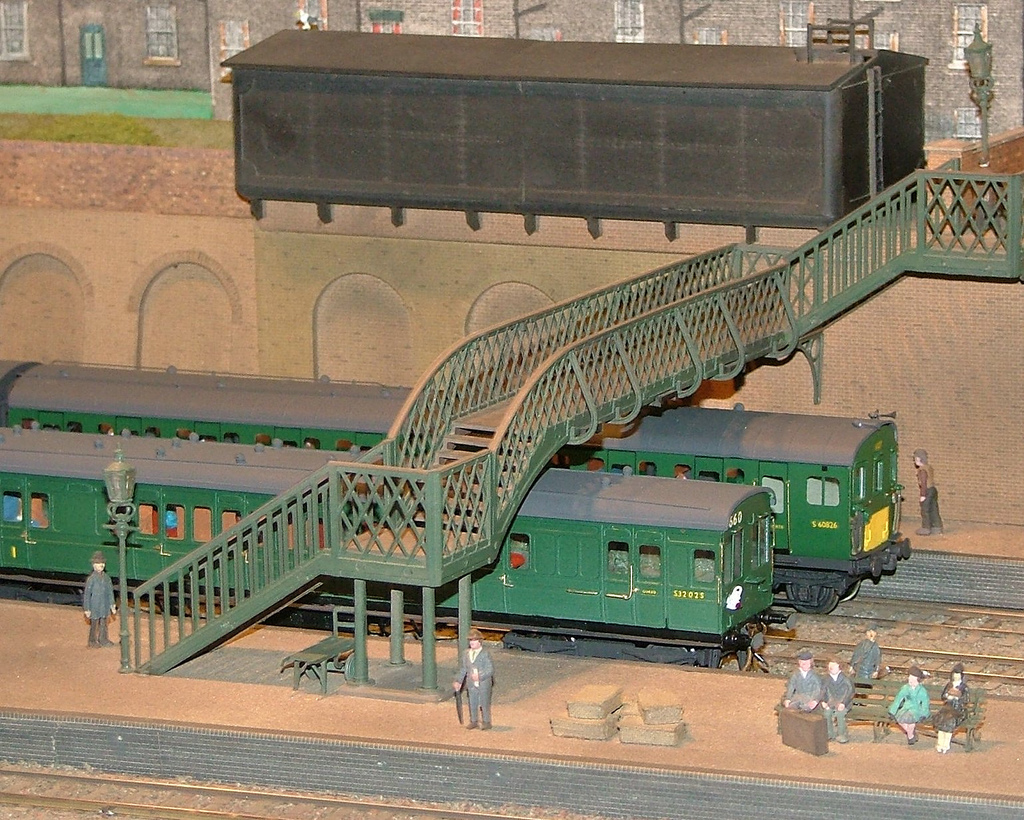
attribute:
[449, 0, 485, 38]
window — glass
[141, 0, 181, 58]
window — glass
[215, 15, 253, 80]
window — glass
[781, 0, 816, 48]
window — glass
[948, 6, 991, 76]
window — glass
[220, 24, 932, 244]
structure — large, brown, wood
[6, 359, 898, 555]
train car — green, gray, passenger train car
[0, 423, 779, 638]
train car — green, grey, passenger train car, gray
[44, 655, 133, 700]
platform — train platform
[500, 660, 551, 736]
platform — train platform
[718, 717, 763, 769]
platform — train platform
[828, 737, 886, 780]
platform — train platform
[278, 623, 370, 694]
bench — tan, wooden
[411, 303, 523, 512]
stairs — green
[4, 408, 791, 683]
train — green